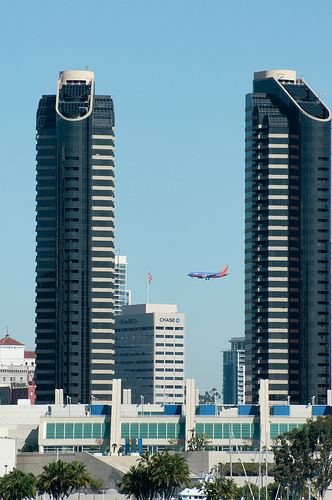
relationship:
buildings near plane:
[27, 46, 331, 401] [177, 263, 239, 291]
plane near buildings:
[177, 263, 239, 291] [27, 46, 331, 401]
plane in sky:
[177, 263, 239, 291] [0, 3, 329, 394]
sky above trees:
[0, 3, 329, 394] [2, 427, 331, 499]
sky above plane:
[0, 3, 329, 394] [177, 263, 239, 291]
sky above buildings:
[0, 3, 329, 394] [27, 46, 331, 401]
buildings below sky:
[27, 46, 331, 401] [0, 3, 329, 394]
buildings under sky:
[27, 46, 331, 401] [0, 3, 329, 394]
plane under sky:
[177, 263, 239, 291] [0, 3, 329, 394]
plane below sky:
[177, 263, 239, 291] [0, 3, 329, 394]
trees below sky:
[2, 427, 331, 499] [0, 3, 329, 394]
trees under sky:
[2, 427, 331, 499] [0, 3, 329, 394]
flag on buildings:
[136, 266, 167, 305] [27, 46, 331, 401]